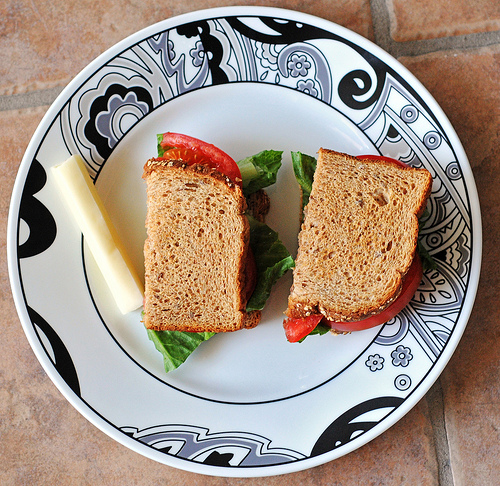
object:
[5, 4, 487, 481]
plate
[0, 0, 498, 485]
surface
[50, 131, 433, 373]
food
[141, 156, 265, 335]
bread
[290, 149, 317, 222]
piece of vegetable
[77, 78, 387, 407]
portion of plate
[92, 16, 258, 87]
design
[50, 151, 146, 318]
cheese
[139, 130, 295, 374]
half of sandwich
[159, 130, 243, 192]
lettuce and tomatoes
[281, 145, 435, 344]
half of sandwich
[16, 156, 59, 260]
decorations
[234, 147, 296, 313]
lettuce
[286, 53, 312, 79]
flower design